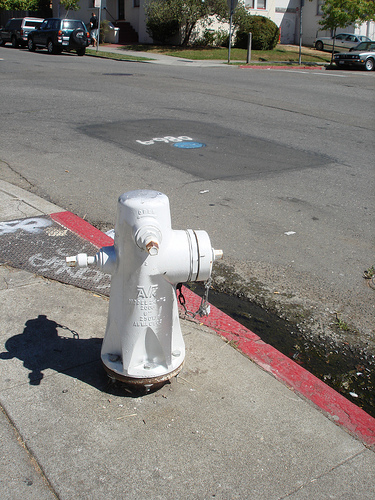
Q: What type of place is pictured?
A: It is a road.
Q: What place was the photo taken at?
A: It was taken at the road.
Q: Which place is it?
A: It is a road.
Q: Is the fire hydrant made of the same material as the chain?
A: Yes, both the fire hydrant and the chain are made of metal.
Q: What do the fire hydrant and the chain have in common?
A: The material, both the fire hydrant and the chain are metallic.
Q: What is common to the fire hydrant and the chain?
A: The material, both the fire hydrant and the chain are metallic.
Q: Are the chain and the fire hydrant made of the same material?
A: Yes, both the chain and the fire hydrant are made of metal.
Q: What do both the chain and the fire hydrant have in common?
A: The material, both the chain and the fire hydrant are metallic.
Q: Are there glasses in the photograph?
A: No, there are no glasses.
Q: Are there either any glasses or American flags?
A: No, there are no glasses or American flags.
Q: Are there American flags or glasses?
A: No, there are no glasses or American flags.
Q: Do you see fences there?
A: No, there are no fences.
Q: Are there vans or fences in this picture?
A: No, there are no fences or vans.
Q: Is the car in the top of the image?
A: Yes, the car is in the top of the image.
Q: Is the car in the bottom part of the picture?
A: No, the car is in the top of the image.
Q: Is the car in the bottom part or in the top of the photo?
A: The car is in the top of the image.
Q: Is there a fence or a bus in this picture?
A: No, there are no fences or buses.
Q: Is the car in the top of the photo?
A: Yes, the car is in the top of the image.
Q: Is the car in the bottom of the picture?
A: No, the car is in the top of the image.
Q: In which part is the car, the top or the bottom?
A: The car is in the top of the image.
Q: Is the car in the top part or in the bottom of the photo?
A: The car is in the top of the image.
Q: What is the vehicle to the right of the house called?
A: The vehicle is a car.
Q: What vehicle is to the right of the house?
A: The vehicle is a car.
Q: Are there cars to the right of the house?
A: Yes, there is a car to the right of the house.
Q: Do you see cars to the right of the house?
A: Yes, there is a car to the right of the house.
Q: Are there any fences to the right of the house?
A: No, there is a car to the right of the house.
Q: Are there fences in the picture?
A: No, there are no fences.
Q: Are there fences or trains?
A: No, there are no fences or trains.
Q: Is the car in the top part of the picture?
A: Yes, the car is in the top of the image.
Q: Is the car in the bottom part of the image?
A: No, the car is in the top of the image.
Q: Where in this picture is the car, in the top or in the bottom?
A: The car is in the top of the image.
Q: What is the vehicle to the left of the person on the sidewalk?
A: The vehicle is a car.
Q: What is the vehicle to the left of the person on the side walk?
A: The vehicle is a car.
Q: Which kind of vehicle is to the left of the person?
A: The vehicle is a car.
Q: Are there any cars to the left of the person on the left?
A: Yes, there is a car to the left of the person.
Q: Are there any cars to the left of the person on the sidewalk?
A: Yes, there is a car to the left of the person.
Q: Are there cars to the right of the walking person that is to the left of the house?
A: No, the car is to the left of the person.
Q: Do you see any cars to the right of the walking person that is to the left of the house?
A: No, the car is to the left of the person.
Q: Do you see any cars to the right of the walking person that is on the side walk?
A: No, the car is to the left of the person.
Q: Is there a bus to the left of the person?
A: No, there is a car to the left of the person.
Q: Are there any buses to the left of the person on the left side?
A: No, there is a car to the left of the person.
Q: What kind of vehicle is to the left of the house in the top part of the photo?
A: The vehicle is a car.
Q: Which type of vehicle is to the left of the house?
A: The vehicle is a car.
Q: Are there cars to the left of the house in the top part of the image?
A: Yes, there is a car to the left of the house.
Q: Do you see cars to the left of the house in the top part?
A: Yes, there is a car to the left of the house.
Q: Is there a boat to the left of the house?
A: No, there is a car to the left of the house.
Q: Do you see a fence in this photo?
A: No, there are no fences.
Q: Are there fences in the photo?
A: No, there are no fences.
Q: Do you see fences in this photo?
A: No, there are no fences.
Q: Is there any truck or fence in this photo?
A: No, there are no fences or trucks.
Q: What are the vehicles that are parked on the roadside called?
A: The vehicles are cars.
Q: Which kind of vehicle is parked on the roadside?
A: The vehicles are cars.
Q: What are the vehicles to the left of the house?
A: The vehicles are cars.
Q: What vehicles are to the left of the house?
A: The vehicles are cars.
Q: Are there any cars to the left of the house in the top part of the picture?
A: Yes, there are cars to the left of the house.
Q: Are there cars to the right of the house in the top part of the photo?
A: No, the cars are to the left of the house.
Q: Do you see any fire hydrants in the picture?
A: Yes, there is a fire hydrant.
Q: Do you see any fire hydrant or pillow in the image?
A: Yes, there is a fire hydrant.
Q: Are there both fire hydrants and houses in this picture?
A: Yes, there are both a fire hydrant and a house.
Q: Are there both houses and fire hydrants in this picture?
A: Yes, there are both a fire hydrant and a house.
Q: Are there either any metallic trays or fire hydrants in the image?
A: Yes, there is a metal fire hydrant.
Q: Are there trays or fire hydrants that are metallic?
A: Yes, the fire hydrant is metallic.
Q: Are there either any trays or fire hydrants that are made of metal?
A: Yes, the fire hydrant is made of metal.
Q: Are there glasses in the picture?
A: No, there are no glasses.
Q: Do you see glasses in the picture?
A: No, there are no glasses.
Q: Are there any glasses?
A: No, there are no glasses.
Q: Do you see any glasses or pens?
A: No, there are no glasses or pens.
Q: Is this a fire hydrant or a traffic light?
A: This is a fire hydrant.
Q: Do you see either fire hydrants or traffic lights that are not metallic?
A: No, there is a fire hydrant but it is metallic.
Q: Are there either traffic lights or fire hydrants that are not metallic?
A: No, there is a fire hydrant but it is metallic.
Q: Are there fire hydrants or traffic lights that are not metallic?
A: No, there is a fire hydrant but it is metallic.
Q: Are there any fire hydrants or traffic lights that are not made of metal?
A: No, there is a fire hydrant but it is made of metal.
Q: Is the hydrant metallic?
A: Yes, the hydrant is metallic.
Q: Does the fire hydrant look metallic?
A: Yes, the fire hydrant is metallic.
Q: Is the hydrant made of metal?
A: Yes, the hydrant is made of metal.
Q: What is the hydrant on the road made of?
A: The fire hydrant is made of metal.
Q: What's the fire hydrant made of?
A: The fire hydrant is made of metal.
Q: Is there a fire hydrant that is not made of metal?
A: No, there is a fire hydrant but it is made of metal.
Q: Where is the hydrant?
A: The hydrant is on the road.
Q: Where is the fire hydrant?
A: The hydrant is on the road.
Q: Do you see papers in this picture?
A: No, there are no papers.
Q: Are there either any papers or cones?
A: No, there are no papers or cones.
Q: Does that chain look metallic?
A: Yes, the chain is metallic.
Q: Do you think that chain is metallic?
A: Yes, the chain is metallic.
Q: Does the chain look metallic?
A: Yes, the chain is metallic.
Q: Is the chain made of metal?
A: Yes, the chain is made of metal.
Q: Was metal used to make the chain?
A: Yes, the chain is made of metal.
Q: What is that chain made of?
A: The chain is made of metal.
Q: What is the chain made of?
A: The chain is made of metal.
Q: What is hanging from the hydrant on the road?
A: The chain is hanging from the hydrant.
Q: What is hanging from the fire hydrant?
A: The chain is hanging from the hydrant.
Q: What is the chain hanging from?
A: The chain is hanging from the hydrant.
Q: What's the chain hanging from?
A: The chain is hanging from the hydrant.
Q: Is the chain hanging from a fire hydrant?
A: Yes, the chain is hanging from a fire hydrant.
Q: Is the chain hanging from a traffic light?
A: No, the chain is hanging from a fire hydrant.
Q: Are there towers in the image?
A: No, there are no towers.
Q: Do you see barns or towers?
A: No, there are no towers or barns.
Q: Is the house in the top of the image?
A: Yes, the house is in the top of the image.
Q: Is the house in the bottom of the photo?
A: No, the house is in the top of the image.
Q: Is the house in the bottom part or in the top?
A: The house is in the top of the image.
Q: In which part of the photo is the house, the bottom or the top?
A: The house is in the top of the image.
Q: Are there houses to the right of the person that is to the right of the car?
A: Yes, there is a house to the right of the person.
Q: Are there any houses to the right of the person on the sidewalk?
A: Yes, there is a house to the right of the person.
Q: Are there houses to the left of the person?
A: No, the house is to the right of the person.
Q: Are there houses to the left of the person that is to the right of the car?
A: No, the house is to the right of the person.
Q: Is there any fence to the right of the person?
A: No, there is a house to the right of the person.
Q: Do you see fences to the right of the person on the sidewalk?
A: No, there is a house to the right of the person.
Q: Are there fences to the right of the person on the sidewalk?
A: No, there is a house to the right of the person.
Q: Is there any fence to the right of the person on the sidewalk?
A: No, there is a house to the right of the person.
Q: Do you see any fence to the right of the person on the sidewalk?
A: No, there is a house to the right of the person.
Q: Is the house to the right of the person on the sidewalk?
A: Yes, the house is to the right of the person.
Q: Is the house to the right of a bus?
A: No, the house is to the right of the person.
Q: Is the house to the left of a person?
A: No, the house is to the right of a person.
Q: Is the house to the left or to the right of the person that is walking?
A: The house is to the right of the person.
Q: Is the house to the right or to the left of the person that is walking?
A: The house is to the right of the person.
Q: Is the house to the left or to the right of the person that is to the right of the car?
A: The house is to the right of the person.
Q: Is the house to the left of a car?
A: Yes, the house is to the left of a car.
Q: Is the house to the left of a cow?
A: No, the house is to the left of a car.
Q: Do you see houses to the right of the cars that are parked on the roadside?
A: Yes, there is a house to the right of the cars.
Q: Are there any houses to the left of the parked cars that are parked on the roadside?
A: No, the house is to the right of the cars.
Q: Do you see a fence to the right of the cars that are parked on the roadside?
A: No, there is a house to the right of the cars.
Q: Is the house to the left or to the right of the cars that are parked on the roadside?
A: The house is to the right of the cars.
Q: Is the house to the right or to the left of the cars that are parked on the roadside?
A: The house is to the right of the cars.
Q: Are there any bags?
A: No, there are no bags.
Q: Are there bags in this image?
A: No, there are no bags.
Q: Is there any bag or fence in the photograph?
A: No, there are no bags or fences.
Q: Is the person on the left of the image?
A: Yes, the person is on the left of the image.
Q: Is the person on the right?
A: No, the person is on the left of the image.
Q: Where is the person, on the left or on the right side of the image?
A: The person is on the left of the image.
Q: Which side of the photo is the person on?
A: The person is on the left of the image.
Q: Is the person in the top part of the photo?
A: Yes, the person is in the top of the image.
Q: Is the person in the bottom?
A: No, the person is in the top of the image.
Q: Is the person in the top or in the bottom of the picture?
A: The person is in the top of the image.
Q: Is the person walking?
A: Yes, the person is walking.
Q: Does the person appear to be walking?
A: Yes, the person is walking.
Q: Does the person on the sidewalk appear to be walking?
A: Yes, the person is walking.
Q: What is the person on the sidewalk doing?
A: The person is walking.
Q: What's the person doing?
A: The person is walking.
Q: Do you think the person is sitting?
A: No, the person is walking.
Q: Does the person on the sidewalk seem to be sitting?
A: No, the person is walking.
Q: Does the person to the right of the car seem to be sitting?
A: No, the person is walking.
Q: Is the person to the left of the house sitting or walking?
A: The person is walking.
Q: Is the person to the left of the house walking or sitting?
A: The person is walking.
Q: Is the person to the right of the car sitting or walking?
A: The person is walking.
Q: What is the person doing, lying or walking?
A: The person is walking.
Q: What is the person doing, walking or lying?
A: The person is walking.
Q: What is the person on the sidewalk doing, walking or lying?
A: The person is walking.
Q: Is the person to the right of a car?
A: Yes, the person is to the right of a car.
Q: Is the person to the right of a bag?
A: No, the person is to the right of a car.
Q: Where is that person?
A: The person is on the sidewalk.